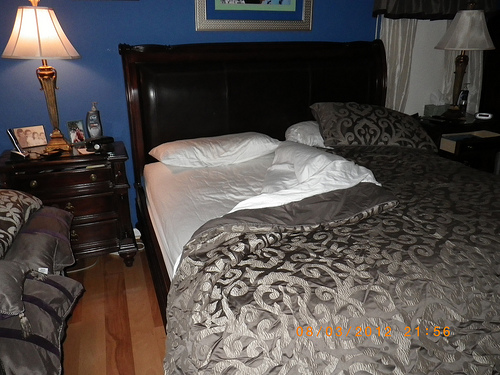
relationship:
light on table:
[0, 0, 82, 152] [1, 140, 139, 267]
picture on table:
[7, 125, 49, 150] [1, 140, 139, 267]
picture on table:
[65, 119, 86, 142] [1, 140, 139, 267]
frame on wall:
[193, 0, 317, 34] [1, 0, 379, 225]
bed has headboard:
[115, 38, 498, 373] [118, 38, 386, 179]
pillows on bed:
[145, 99, 440, 170] [115, 38, 498, 373]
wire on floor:
[64, 240, 145, 273] [63, 239, 176, 374]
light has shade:
[0, 0, 82, 152] [1, 2, 80, 63]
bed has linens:
[115, 38, 498, 373] [139, 123, 376, 282]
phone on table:
[84, 135, 113, 146] [1, 140, 139, 267]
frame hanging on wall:
[192, 1, 313, 32] [1, 0, 379, 225]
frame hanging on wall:
[193, 0, 317, 34] [1, 0, 379, 225]